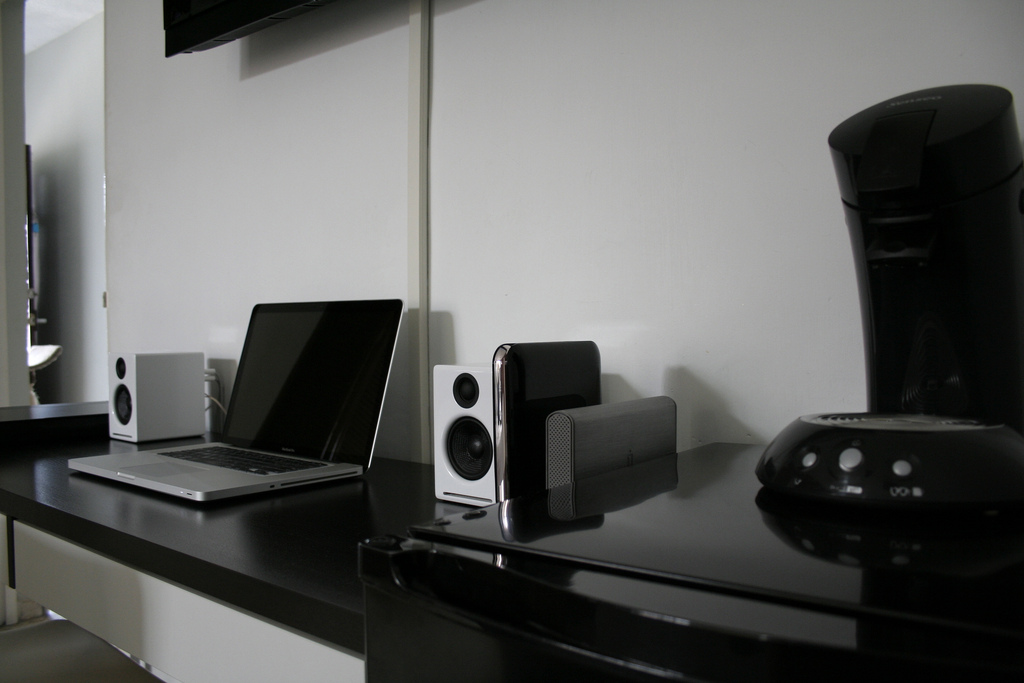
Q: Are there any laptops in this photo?
A: Yes, there is a laptop.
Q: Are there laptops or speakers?
A: Yes, there is a laptop.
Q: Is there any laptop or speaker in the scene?
A: Yes, there is a laptop.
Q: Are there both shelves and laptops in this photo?
A: No, there is a laptop but no shelves.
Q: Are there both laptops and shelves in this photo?
A: No, there is a laptop but no shelves.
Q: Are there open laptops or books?
A: Yes, there is an open laptop.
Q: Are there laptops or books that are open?
A: Yes, the laptop is open.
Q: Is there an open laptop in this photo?
A: Yes, there is an open laptop.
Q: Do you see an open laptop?
A: Yes, there is an open laptop.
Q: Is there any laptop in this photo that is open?
A: Yes, there is a laptop that is open.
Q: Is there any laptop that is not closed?
A: Yes, there is a open laptop.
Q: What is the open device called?
A: The device is a laptop.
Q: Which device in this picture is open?
A: The device is a laptop.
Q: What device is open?
A: The device is a laptop.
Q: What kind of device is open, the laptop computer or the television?
A: The laptop computer is open.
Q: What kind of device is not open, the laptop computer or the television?
A: The television is not open.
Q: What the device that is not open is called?
A: The device is a television.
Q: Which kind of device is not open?
A: The device is a television.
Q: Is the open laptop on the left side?
A: Yes, the laptop is on the left of the image.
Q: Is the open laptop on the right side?
A: No, the laptop is on the left of the image.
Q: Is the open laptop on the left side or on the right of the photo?
A: The laptop is on the left of the image.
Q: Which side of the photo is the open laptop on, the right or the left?
A: The laptop is on the left of the image.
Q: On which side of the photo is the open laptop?
A: The laptop computer is on the left of the image.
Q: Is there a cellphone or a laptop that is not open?
A: No, there is a laptop but it is open.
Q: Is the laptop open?
A: Yes, the laptop is open.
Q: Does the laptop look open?
A: Yes, the laptop is open.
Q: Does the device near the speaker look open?
A: Yes, the laptop is open.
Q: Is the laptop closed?
A: No, the laptop is open.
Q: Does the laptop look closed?
A: No, the laptop is open.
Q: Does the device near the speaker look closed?
A: No, the laptop is open.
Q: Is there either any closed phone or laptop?
A: No, there is a laptop but it is open.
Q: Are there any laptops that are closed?
A: No, there is a laptop but it is open.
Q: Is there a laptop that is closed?
A: No, there is a laptop but it is open.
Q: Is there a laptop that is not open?
A: No, there is a laptop but it is open.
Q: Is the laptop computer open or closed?
A: The laptop computer is open.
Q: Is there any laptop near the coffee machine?
A: Yes, there is a laptop near the coffee machine.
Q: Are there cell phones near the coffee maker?
A: No, there is a laptop near the coffee maker.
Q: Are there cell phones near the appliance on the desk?
A: No, there is a laptop near the coffee maker.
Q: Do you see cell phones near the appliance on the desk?
A: No, there is a laptop near the coffee maker.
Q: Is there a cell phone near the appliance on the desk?
A: No, there is a laptop near the coffee maker.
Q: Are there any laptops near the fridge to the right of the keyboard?
A: Yes, there is a laptop near the refrigerator.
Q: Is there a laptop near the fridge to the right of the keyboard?
A: Yes, there is a laptop near the refrigerator.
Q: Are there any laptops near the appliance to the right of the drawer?
A: Yes, there is a laptop near the refrigerator.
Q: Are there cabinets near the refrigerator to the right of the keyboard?
A: No, there is a laptop near the refrigerator.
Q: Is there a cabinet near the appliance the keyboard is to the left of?
A: No, there is a laptop near the refrigerator.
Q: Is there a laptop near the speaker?
A: Yes, there is a laptop near the speaker.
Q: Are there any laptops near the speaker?
A: Yes, there is a laptop near the speaker.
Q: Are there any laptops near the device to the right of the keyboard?
A: Yes, there is a laptop near the speaker.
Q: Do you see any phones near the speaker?
A: No, there is a laptop near the speaker.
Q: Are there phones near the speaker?
A: No, there is a laptop near the speaker.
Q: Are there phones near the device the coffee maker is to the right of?
A: No, there is a laptop near the speaker.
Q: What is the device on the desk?
A: The device is a laptop.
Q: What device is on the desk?
A: The device is a laptop.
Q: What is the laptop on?
A: The laptop is on the desk.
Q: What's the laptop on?
A: The laptop is on the desk.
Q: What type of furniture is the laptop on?
A: The laptop is on the desk.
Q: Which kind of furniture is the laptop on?
A: The laptop is on the desk.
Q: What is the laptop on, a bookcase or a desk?
A: The laptop is on a desk.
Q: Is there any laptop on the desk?
A: Yes, there is a laptop on the desk.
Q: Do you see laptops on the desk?
A: Yes, there is a laptop on the desk.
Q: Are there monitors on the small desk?
A: No, there is a laptop on the desk.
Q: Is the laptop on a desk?
A: Yes, the laptop is on a desk.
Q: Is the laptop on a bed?
A: No, the laptop is on a desk.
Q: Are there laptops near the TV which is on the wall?
A: Yes, there is a laptop near the television.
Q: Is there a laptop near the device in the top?
A: Yes, there is a laptop near the television.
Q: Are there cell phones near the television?
A: No, there is a laptop near the television.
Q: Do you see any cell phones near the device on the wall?
A: No, there is a laptop near the television.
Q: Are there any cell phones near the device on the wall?
A: No, there is a laptop near the television.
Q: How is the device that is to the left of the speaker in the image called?
A: The device is a laptop.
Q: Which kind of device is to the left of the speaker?
A: The device is a laptop.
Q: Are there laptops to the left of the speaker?
A: Yes, there is a laptop to the left of the speaker.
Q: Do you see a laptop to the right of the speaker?
A: No, the laptop is to the left of the speaker.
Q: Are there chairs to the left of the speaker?
A: No, there is a laptop to the left of the speaker.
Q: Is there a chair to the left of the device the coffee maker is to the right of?
A: No, there is a laptop to the left of the speaker.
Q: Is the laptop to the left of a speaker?
A: Yes, the laptop is to the left of a speaker.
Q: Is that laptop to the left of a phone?
A: No, the laptop is to the left of a speaker.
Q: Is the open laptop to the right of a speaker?
A: No, the laptop is to the left of a speaker.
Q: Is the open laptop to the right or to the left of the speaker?
A: The laptop is to the left of the speaker.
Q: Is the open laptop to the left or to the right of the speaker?
A: The laptop is to the left of the speaker.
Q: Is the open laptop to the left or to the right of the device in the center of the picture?
A: The laptop is to the left of the speaker.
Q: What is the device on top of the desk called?
A: The device is a laptop.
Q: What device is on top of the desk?
A: The device is a laptop.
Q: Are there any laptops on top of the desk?
A: Yes, there is a laptop on top of the desk.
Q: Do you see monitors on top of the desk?
A: No, there is a laptop on top of the desk.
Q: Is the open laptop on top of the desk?
A: Yes, the laptop is on top of the desk.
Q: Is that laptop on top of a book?
A: No, the laptop is on top of the desk.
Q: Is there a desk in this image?
A: Yes, there is a desk.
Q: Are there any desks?
A: Yes, there is a desk.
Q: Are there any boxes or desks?
A: Yes, there is a desk.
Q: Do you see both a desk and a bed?
A: No, there is a desk but no beds.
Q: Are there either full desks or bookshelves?
A: Yes, there is a full desk.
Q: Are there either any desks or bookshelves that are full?
A: Yes, the desk is full.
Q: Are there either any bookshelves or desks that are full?
A: Yes, the desk is full.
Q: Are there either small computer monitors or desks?
A: Yes, there is a small desk.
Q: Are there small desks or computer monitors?
A: Yes, there is a small desk.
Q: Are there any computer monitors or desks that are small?
A: Yes, the desk is small.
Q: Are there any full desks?
A: Yes, there is a full desk.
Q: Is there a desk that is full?
A: Yes, there is a desk that is full.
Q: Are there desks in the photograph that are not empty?
A: Yes, there is an full desk.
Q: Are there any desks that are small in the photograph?
A: Yes, there is a small desk.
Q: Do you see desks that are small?
A: Yes, there is a small desk.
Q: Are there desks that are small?
A: Yes, there is a desk that is small.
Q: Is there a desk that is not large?
A: Yes, there is a small desk.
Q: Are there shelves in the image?
A: No, there are no shelves.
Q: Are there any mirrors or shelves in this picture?
A: No, there are no shelves or mirrors.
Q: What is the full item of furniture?
A: The piece of furniture is a desk.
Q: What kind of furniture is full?
A: The furniture is a desk.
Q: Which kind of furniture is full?
A: The furniture is a desk.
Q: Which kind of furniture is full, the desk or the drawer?
A: The desk is full.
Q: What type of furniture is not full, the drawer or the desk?
A: The drawer is not full.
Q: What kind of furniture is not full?
A: The furniture is a drawer.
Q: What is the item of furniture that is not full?
A: The piece of furniture is a drawer.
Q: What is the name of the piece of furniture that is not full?
A: The piece of furniture is a drawer.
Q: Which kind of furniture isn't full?
A: The furniture is a drawer.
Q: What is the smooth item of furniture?
A: The piece of furniture is a desk.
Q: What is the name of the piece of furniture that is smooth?
A: The piece of furniture is a desk.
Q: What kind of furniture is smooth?
A: The furniture is a desk.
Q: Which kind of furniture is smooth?
A: The furniture is a desk.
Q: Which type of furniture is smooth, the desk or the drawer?
A: The desk is smooth.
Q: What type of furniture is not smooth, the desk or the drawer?
A: The drawer is not smooth.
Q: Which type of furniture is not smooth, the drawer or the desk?
A: The drawer is not smooth.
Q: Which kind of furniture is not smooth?
A: The furniture is a drawer.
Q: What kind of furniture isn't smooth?
A: The furniture is a drawer.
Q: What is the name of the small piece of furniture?
A: The piece of furniture is a desk.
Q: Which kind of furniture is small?
A: The furniture is a desk.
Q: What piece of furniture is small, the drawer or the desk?
A: The desk is small.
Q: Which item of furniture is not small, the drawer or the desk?
A: The drawer is not small.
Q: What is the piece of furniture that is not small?
A: The piece of furniture is a drawer.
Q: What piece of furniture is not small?
A: The piece of furniture is a drawer.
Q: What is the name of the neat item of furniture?
A: The piece of furniture is a desk.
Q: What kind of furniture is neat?
A: The furniture is a desk.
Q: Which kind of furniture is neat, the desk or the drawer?
A: The desk is neat.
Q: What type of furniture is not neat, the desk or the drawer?
A: The drawer is not neat.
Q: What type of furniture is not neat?
A: The furniture is a drawer.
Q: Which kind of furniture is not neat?
A: The furniture is a drawer.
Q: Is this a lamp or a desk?
A: This is a desk.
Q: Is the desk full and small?
A: Yes, the desk is full and small.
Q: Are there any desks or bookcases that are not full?
A: No, there is a desk but it is full.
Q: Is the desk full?
A: Yes, the desk is full.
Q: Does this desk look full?
A: Yes, the desk is full.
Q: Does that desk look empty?
A: No, the desk is full.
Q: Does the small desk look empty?
A: No, the desk is full.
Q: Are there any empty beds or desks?
A: No, there is a desk but it is full.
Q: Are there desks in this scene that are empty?
A: No, there is a desk but it is full.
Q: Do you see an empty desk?
A: No, there is a desk but it is full.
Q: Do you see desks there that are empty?
A: No, there is a desk but it is full.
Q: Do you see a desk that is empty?
A: No, there is a desk but it is full.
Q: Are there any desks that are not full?
A: No, there is a desk but it is full.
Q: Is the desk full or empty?
A: The desk is full.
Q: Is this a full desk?
A: Yes, this is a full desk.